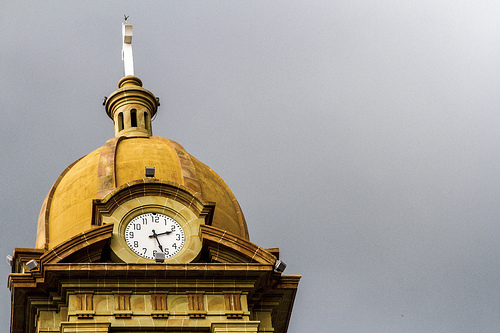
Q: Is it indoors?
A: Yes, it is indoors.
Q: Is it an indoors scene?
A: Yes, it is indoors.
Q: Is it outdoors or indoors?
A: It is indoors.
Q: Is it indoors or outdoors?
A: It is indoors.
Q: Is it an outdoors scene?
A: No, it is indoors.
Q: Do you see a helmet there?
A: No, there are no helmets.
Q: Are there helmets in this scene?
A: No, there are no helmets.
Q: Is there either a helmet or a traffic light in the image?
A: No, there are no helmets or traffic lights.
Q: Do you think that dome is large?
A: Yes, the dome is large.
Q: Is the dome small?
A: No, the dome is large.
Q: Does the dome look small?
A: No, the dome is large.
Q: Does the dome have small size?
A: No, the dome is large.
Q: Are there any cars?
A: No, there are no cars.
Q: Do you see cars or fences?
A: No, there are no cars or fences.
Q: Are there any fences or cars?
A: No, there are no cars or fences.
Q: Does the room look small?
A: Yes, the room is small.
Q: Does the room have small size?
A: Yes, the room is small.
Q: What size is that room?
A: The room is small.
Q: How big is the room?
A: The room is small.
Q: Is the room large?
A: No, the room is small.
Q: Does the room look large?
A: No, the room is small.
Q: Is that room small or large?
A: The room is small.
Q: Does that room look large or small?
A: The room is small.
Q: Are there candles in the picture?
A: No, there are no candles.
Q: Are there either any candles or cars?
A: No, there are no candles or cars.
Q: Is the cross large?
A: Yes, the cross is large.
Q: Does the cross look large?
A: Yes, the cross is large.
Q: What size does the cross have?
A: The cross has large size.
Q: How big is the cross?
A: The cross is large.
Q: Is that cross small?
A: No, the cross is large.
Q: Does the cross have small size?
A: No, the cross is large.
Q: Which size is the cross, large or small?
A: The cross is large.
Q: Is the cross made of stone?
A: Yes, the cross is made of stone.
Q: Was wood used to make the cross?
A: No, the cross is made of stone.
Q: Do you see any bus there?
A: No, there are no buses.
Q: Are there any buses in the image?
A: No, there are no buses.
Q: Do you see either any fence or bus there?
A: No, there are no buses or fences.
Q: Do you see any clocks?
A: Yes, there is a clock.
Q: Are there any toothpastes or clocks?
A: Yes, there is a clock.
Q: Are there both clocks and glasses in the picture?
A: No, there is a clock but no glasses.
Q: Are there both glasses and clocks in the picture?
A: No, there is a clock but no glasses.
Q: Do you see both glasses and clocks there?
A: No, there is a clock but no glasses.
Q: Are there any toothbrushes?
A: No, there are no toothbrushes.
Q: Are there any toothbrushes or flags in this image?
A: No, there are no toothbrushes or flags.